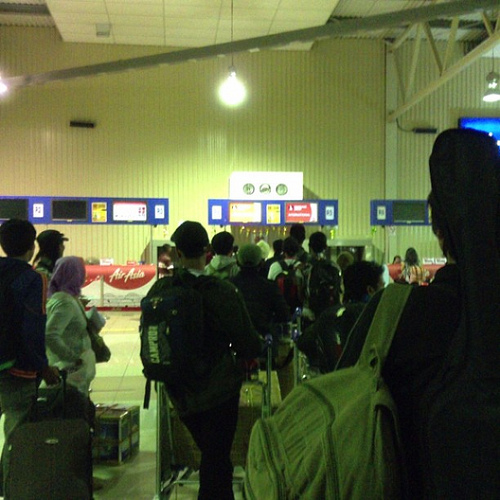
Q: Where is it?
A: This is at the airport.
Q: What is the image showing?
A: It is showing an airport.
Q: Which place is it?
A: It is an airport.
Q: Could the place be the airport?
A: Yes, it is the airport.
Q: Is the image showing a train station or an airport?
A: It is showing an airport.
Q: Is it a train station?
A: No, it is an airport.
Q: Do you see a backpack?
A: Yes, there is a backpack.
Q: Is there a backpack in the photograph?
A: Yes, there is a backpack.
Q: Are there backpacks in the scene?
A: Yes, there is a backpack.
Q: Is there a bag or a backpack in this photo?
A: Yes, there is a backpack.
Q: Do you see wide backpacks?
A: Yes, there is a wide backpack.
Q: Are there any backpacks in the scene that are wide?
A: Yes, there is a backpack that is wide.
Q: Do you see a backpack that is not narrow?
A: Yes, there is a wide backpack.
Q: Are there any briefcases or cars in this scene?
A: No, there are no cars or briefcases.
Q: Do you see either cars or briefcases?
A: No, there are no cars or briefcases.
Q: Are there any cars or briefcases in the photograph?
A: No, there are no cars or briefcases.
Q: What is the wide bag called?
A: The bag is a backpack.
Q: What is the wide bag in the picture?
A: The bag is a backpack.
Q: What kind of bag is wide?
A: The bag is a backpack.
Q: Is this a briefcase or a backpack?
A: This is a backpack.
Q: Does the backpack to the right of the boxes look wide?
A: Yes, the backpack is wide.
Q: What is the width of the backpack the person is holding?
A: The backpack is wide.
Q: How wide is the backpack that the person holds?
A: The backpack is wide.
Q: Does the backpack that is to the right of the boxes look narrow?
A: No, the backpack is wide.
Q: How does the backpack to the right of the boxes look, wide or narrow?
A: The backpack is wide.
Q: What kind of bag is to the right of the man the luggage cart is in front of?
A: The bag is a backpack.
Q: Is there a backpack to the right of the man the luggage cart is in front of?
A: Yes, there is a backpack to the right of the man.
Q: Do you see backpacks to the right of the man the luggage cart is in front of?
A: Yes, there is a backpack to the right of the man.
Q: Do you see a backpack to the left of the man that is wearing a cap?
A: No, the backpack is to the right of the man.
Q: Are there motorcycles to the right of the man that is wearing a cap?
A: No, there is a backpack to the right of the man.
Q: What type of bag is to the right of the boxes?
A: The bag is a backpack.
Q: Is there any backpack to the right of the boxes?
A: Yes, there is a backpack to the right of the boxes.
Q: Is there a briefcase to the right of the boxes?
A: No, there is a backpack to the right of the boxes.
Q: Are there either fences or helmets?
A: No, there are no helmets or fences.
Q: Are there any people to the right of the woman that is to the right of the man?
A: Yes, there is a person to the right of the woman.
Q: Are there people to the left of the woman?
A: No, the person is to the right of the woman.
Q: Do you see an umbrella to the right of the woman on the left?
A: No, there is a person to the right of the woman.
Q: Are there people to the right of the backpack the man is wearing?
A: Yes, there is a person to the right of the backpack.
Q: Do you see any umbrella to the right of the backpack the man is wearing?
A: No, there is a person to the right of the backpack.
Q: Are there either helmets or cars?
A: No, there are no cars or helmets.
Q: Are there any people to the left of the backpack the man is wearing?
A: Yes, there is a person to the left of the backpack.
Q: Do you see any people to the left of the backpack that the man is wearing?
A: Yes, there is a person to the left of the backpack.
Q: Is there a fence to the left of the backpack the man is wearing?
A: No, there is a person to the left of the backpack.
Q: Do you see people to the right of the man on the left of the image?
A: Yes, there is a person to the right of the man.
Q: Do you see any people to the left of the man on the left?
A: No, the person is to the right of the man.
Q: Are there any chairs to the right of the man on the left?
A: No, there is a person to the right of the man.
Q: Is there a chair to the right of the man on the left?
A: No, there is a person to the right of the man.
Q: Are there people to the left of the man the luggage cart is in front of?
A: Yes, there is a person to the left of the man.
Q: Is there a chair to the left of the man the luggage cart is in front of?
A: No, there is a person to the left of the man.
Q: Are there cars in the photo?
A: No, there are no cars.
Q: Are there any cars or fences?
A: No, there are no cars or fences.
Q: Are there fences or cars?
A: No, there are no cars or fences.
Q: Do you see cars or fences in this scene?
A: No, there are no cars or fences.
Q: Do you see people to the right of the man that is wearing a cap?
A: Yes, there is a person to the right of the man.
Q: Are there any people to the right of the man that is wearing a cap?
A: Yes, there is a person to the right of the man.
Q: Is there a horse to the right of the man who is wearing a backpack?
A: No, there is a person to the right of the man.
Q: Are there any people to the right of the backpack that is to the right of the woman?
A: Yes, there is a person to the right of the backpack.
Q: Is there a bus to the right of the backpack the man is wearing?
A: No, there is a person to the right of the backpack.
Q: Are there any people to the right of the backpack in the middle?
A: Yes, there is a person to the right of the backpack.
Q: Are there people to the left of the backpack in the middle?
A: No, the person is to the right of the backpack.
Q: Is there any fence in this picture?
A: No, there are no fences.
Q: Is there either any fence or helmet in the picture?
A: No, there are no fences or helmets.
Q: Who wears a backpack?
A: The man wears a backpack.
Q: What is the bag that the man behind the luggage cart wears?
A: The bag is a backpack.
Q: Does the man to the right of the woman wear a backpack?
A: Yes, the man wears a backpack.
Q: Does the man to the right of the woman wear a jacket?
A: No, the man wears a backpack.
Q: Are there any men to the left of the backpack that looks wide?
A: Yes, there is a man to the left of the backpack.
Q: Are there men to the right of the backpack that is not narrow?
A: No, the man is to the left of the backpack.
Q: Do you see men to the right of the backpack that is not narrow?
A: No, the man is to the left of the backpack.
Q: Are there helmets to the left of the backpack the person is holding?
A: No, there is a man to the left of the backpack.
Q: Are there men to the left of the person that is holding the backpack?
A: Yes, there is a man to the left of the person.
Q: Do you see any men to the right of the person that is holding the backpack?
A: No, the man is to the left of the person.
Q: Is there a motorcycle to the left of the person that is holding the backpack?
A: No, there is a man to the left of the person.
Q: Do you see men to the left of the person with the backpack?
A: Yes, there is a man to the left of the person.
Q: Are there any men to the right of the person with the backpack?
A: No, the man is to the left of the person.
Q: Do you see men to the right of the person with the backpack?
A: No, the man is to the left of the person.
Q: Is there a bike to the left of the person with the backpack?
A: No, there is a man to the left of the person.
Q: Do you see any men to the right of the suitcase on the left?
A: Yes, there is a man to the right of the suitcase.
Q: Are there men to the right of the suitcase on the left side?
A: Yes, there is a man to the right of the suitcase.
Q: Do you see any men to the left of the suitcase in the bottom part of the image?
A: No, the man is to the right of the suitcase.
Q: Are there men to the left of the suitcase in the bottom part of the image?
A: No, the man is to the right of the suitcase.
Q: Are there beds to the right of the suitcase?
A: No, there is a man to the right of the suitcase.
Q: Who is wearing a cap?
A: The man is wearing a cap.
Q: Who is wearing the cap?
A: The man is wearing a cap.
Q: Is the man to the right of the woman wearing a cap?
A: Yes, the man is wearing a cap.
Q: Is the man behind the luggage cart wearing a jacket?
A: No, the man is wearing a cap.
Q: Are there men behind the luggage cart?
A: Yes, there is a man behind the luggage cart.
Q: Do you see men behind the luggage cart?
A: Yes, there is a man behind the luggage cart.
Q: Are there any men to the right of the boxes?
A: Yes, there is a man to the right of the boxes.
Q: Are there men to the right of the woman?
A: Yes, there is a man to the right of the woman.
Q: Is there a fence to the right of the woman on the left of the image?
A: No, there is a man to the right of the woman.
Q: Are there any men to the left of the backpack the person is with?
A: Yes, there is a man to the left of the backpack.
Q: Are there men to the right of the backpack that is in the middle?
A: No, the man is to the left of the backpack.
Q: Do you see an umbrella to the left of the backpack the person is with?
A: No, there is a man to the left of the backpack.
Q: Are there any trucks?
A: No, there are no trucks.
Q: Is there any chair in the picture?
A: No, there are no chairs.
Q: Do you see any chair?
A: No, there are no chairs.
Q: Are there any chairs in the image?
A: No, there are no chairs.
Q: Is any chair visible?
A: No, there are no chairs.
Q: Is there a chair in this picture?
A: No, there are no chairs.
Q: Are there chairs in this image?
A: No, there are no chairs.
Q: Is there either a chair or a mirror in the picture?
A: No, there are no chairs or mirrors.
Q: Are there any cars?
A: No, there are no cars.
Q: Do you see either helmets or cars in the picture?
A: No, there are no cars or helmets.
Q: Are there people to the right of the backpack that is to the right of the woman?
A: Yes, there is a person to the right of the backpack.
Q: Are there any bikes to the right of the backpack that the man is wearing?
A: No, there is a person to the right of the backpack.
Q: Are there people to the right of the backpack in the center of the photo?
A: Yes, there is a person to the right of the backpack.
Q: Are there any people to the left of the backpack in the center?
A: No, the person is to the right of the backpack.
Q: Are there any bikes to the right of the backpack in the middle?
A: No, there is a person to the right of the backpack.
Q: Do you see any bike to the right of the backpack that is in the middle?
A: No, there is a person to the right of the backpack.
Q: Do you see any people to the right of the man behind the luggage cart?
A: Yes, there is a person to the right of the man.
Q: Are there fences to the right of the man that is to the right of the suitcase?
A: No, there is a person to the right of the man.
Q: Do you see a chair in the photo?
A: No, there are no chairs.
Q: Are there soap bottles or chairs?
A: No, there are no chairs or soap bottles.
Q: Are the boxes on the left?
A: Yes, the boxes are on the left of the image.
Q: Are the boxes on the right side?
A: No, the boxes are on the left of the image.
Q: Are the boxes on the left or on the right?
A: The boxes are on the left of the image.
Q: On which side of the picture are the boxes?
A: The boxes are on the left of the image.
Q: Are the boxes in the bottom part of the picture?
A: Yes, the boxes are in the bottom of the image.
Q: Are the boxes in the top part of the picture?
A: No, the boxes are in the bottom of the image.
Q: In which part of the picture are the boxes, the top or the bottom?
A: The boxes are in the bottom of the image.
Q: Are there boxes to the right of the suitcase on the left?
A: Yes, there are boxes to the right of the suitcase.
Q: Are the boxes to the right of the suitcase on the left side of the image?
A: Yes, the boxes are to the right of the suitcase.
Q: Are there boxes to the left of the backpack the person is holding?
A: Yes, there are boxes to the left of the backpack.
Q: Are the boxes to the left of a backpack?
A: Yes, the boxes are to the left of a backpack.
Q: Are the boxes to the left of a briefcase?
A: No, the boxes are to the left of a backpack.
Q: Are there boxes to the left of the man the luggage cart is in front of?
A: Yes, there are boxes to the left of the man.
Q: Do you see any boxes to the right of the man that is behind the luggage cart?
A: No, the boxes are to the left of the man.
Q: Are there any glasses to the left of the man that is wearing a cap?
A: No, there are boxes to the left of the man.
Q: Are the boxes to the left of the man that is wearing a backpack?
A: Yes, the boxes are to the left of the man.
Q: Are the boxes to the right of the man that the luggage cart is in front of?
A: No, the boxes are to the left of the man.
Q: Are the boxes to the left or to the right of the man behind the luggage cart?
A: The boxes are to the left of the man.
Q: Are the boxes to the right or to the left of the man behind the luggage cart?
A: The boxes are to the left of the man.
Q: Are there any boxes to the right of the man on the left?
A: Yes, there are boxes to the right of the man.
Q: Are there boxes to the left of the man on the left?
A: No, the boxes are to the right of the man.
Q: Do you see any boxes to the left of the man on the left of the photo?
A: No, the boxes are to the right of the man.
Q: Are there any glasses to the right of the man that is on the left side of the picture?
A: No, there are boxes to the right of the man.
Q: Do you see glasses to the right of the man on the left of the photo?
A: No, there are boxes to the right of the man.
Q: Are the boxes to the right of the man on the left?
A: Yes, the boxes are to the right of the man.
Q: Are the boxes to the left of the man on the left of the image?
A: No, the boxes are to the right of the man.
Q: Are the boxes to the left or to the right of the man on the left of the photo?
A: The boxes are to the right of the man.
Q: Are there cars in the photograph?
A: No, there are no cars.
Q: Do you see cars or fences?
A: No, there are no cars or fences.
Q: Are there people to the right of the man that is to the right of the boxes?
A: Yes, there is a person to the right of the man.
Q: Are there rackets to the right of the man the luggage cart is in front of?
A: No, there is a person to the right of the man.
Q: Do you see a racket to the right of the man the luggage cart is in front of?
A: No, there is a person to the right of the man.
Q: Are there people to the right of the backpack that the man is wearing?
A: Yes, there is a person to the right of the backpack.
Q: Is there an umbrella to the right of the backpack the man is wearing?
A: No, there is a person to the right of the backpack.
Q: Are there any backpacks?
A: Yes, there is a backpack.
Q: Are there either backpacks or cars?
A: Yes, there is a backpack.